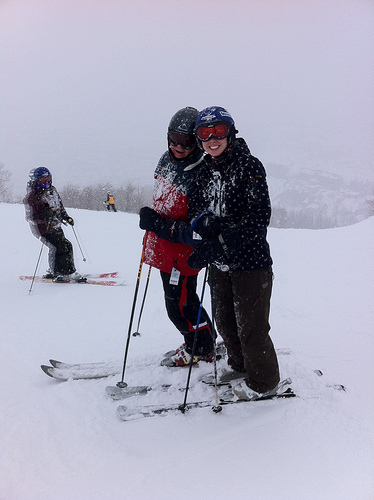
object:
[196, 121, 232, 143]
goggles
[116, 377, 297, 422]
skis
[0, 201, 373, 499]
snow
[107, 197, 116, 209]
coat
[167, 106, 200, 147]
helmet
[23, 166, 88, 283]
people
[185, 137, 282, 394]
clothing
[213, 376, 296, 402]
boots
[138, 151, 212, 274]
coat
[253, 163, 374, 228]
mountain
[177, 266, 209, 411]
poles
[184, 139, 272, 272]
jacket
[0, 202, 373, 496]
ground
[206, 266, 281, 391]
pants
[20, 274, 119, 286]
skis